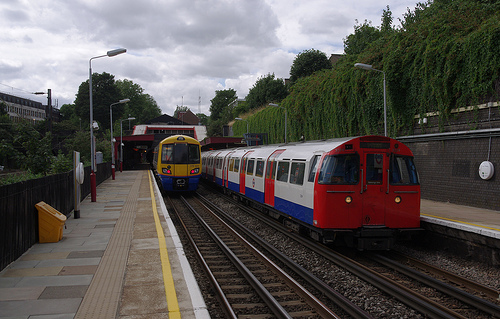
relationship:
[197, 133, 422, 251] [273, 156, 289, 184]
train has window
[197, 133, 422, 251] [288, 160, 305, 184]
train has window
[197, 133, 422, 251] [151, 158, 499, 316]
train on tracks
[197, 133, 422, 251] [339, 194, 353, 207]
train has headlights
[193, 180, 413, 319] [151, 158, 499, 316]
gravel between tracks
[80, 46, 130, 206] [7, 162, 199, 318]
light on platform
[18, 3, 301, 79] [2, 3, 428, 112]
cloud in sky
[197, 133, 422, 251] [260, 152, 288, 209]
train has door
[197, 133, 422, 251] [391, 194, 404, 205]
train has light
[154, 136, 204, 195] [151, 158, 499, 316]
train on tracks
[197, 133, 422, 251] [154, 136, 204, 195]
train next to train